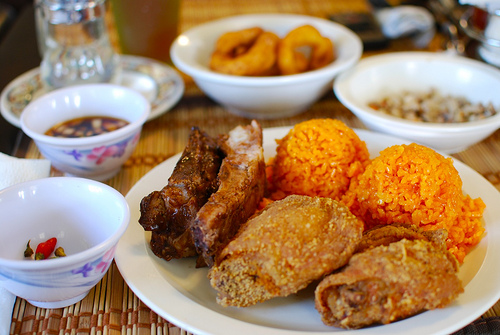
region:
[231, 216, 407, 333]
two pieces of fried chicken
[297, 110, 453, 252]
two scoops of rice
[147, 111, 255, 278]
two ribs on a plate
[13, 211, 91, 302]
small bowl of peppers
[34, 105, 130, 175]
small bowl of sauce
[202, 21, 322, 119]
onion rings in white bowl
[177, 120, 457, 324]
plate of southern food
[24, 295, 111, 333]
wicker placemat under food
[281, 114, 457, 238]
two helpings of orange rice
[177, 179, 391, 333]
fried chicken and ribs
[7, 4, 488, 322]
chinese food on a bamboo placemat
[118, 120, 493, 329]
white plate with Chinese food on it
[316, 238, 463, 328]
fried egg roll on a white plate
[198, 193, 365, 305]
egg roll on a white plate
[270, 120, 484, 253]
two mounds of rice on a white plate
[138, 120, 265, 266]
two ribs on a white plate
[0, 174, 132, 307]
white porcelain bowl with blue decoration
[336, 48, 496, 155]
white bowl with food in it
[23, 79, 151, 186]
white bowl with a dark brown sauce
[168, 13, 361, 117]
white bowl with fried rings of food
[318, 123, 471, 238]
two balls of yellow rice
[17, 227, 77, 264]
pieces of small peppers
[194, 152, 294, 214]
two pieces of ribs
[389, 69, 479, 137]
small cup of colored beans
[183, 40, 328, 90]
two pieces of onion rings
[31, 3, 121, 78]
clear bottle of water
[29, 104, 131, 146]
bowl of beef soup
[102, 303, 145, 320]
bamboo designed placemat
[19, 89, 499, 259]
dinner plates and bowls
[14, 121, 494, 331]
bamboo placemat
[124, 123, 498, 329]
plate full of food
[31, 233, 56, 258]
small red pepper in the bowl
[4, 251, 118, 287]
pink and purple flowers on the bowl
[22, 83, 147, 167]
white bowl with sauce in it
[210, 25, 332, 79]
fried food in the serving bowl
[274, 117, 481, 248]
two scoops of cooked rice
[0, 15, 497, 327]
table of white dishes filled with food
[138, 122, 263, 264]
meat on the plate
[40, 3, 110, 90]
glass pepper grinder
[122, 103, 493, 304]
a plate with food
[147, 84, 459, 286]
a white plate with food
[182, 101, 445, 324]
food on a table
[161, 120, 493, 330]
plate on a table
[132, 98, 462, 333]
white plate on a table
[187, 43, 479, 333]
two stackes of rice on aplate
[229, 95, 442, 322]
two stacks of rice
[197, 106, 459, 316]
rice on a plate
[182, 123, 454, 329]
rice on a white plate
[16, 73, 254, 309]
white bowls on the table